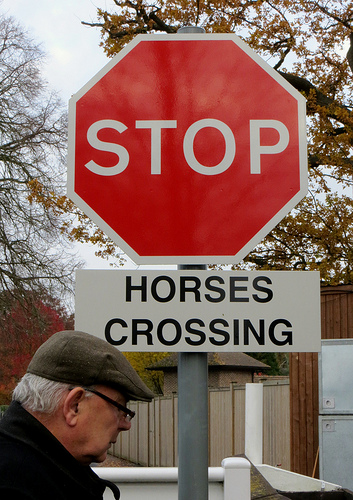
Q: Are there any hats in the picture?
A: Yes, there is a hat.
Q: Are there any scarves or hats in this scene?
A: Yes, there is a hat.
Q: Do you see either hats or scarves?
A: Yes, there is a hat.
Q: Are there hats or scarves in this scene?
A: Yes, there is a hat.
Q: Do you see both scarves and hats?
A: No, there is a hat but no scarves.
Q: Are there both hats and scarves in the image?
A: No, there is a hat but no scarves.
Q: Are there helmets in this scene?
A: No, there are no helmets.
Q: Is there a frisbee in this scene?
A: No, there are no frisbees.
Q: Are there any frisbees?
A: No, there are no frisbees.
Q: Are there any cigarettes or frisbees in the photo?
A: No, there are no frisbees or cigarettes.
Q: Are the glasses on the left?
A: Yes, the glasses are on the left of the image.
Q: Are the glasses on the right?
A: No, the glasses are on the left of the image.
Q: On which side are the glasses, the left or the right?
A: The glasses are on the left of the image.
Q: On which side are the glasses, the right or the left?
A: The glasses are on the left of the image.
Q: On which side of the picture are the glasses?
A: The glasses are on the left of the image.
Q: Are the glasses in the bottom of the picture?
A: Yes, the glasses are in the bottom of the image.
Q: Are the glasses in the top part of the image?
A: No, the glasses are in the bottom of the image.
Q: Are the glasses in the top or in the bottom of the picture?
A: The glasses are in the bottom of the image.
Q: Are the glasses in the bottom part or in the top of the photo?
A: The glasses are in the bottom of the image.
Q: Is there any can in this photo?
A: No, there are no cans.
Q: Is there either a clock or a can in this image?
A: No, there are no cans or clocks.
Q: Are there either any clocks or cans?
A: No, there are no cans or clocks.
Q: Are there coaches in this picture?
A: No, there are no coaches.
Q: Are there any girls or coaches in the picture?
A: No, there are no coaches or girls.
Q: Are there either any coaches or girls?
A: No, there are no coaches or girls.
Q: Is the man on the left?
A: Yes, the man is on the left of the image.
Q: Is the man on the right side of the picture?
A: No, the man is on the left of the image.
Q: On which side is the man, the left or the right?
A: The man is on the left of the image.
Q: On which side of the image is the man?
A: The man is on the left of the image.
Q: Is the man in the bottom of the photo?
A: Yes, the man is in the bottom of the image.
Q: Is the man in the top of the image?
A: No, the man is in the bottom of the image.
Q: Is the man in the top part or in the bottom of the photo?
A: The man is in the bottom of the image.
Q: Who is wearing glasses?
A: The man is wearing glasses.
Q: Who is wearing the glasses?
A: The man is wearing glasses.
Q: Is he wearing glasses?
A: Yes, the man is wearing glasses.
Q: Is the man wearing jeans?
A: No, the man is wearing glasses.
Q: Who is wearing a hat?
A: The man is wearing a hat.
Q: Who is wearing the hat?
A: The man is wearing a hat.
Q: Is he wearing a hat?
A: Yes, the man is wearing a hat.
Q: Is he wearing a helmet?
A: No, the man is wearing a hat.